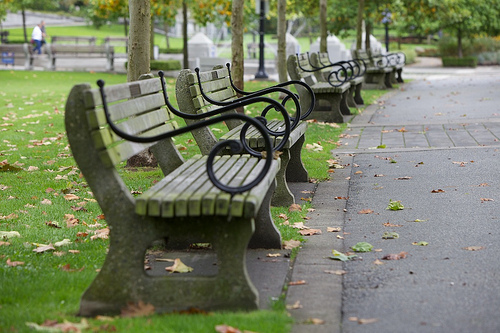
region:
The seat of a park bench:
[127, 140, 287, 228]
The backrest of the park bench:
[41, 68, 178, 158]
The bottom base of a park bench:
[69, 218, 278, 313]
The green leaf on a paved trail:
[386, 191, 406, 213]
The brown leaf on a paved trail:
[383, 246, 411, 265]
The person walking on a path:
[19, 19, 52, 75]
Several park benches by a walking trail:
[68, 33, 414, 315]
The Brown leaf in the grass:
[5, 255, 28, 272]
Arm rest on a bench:
[208, 108, 278, 203]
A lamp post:
[381, 7, 396, 60]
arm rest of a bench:
[113, 98, 285, 185]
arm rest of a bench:
[180, 88, 290, 118]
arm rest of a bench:
[196, 82, 297, 109]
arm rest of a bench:
[223, 73, 325, 89]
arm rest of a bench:
[303, 60, 351, 82]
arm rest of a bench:
[334, 57, 362, 65]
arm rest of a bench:
[359, 54, 371, 73]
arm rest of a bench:
[374, 48, 396, 70]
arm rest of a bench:
[385, 48, 407, 60]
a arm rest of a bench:
[152, 99, 285, 174]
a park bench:
[31, 55, 315, 321]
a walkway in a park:
[379, 103, 497, 318]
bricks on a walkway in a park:
[372, 115, 498, 153]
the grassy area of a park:
[9, 84, 68, 252]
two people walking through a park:
[26, 16, 63, 57]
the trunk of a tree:
[117, 12, 159, 62]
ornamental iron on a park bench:
[92, 75, 295, 190]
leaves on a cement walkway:
[313, 193, 423, 272]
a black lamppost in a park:
[252, 7, 274, 81]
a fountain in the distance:
[167, 10, 237, 54]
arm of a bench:
[152, 108, 283, 173]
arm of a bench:
[225, 92, 293, 120]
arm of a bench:
[237, 70, 300, 99]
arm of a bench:
[285, 70, 325, 92]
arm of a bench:
[312, 57, 347, 78]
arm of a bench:
[345, 52, 366, 72]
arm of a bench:
[366, 53, 393, 67]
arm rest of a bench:
[179, 110, 274, 170]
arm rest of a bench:
[240, 70, 308, 117]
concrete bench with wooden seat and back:
[56, 70, 288, 315]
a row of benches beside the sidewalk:
[39, 43, 422, 323]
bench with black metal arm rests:
[60, 67, 298, 317]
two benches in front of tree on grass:
[45, 56, 314, 321]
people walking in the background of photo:
[23, 15, 72, 62]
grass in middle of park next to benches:
[0, 66, 407, 330]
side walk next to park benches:
[284, 50, 497, 332]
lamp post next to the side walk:
[379, 10, 401, 54]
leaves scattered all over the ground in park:
[6, 63, 498, 332]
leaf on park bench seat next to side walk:
[253, 142, 287, 162]